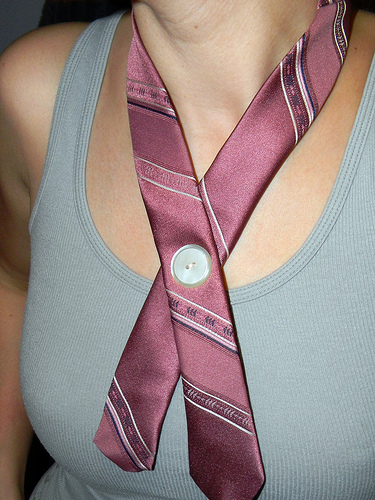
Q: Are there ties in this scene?
A: Yes, there is a tie.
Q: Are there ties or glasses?
A: Yes, there is a tie.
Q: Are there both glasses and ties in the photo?
A: No, there is a tie but no glasses.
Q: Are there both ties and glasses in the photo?
A: No, there is a tie but no glasses.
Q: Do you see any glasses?
A: No, there are no glasses.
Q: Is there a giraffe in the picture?
A: No, there are no giraffes.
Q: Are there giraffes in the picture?
A: No, there are no giraffes.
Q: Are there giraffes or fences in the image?
A: No, there are no giraffes or fences.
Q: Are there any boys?
A: No, there are no boys.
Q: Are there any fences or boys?
A: No, there are no boys or fences.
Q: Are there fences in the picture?
A: No, there are no fences.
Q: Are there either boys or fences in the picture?
A: No, there are no fences or boys.